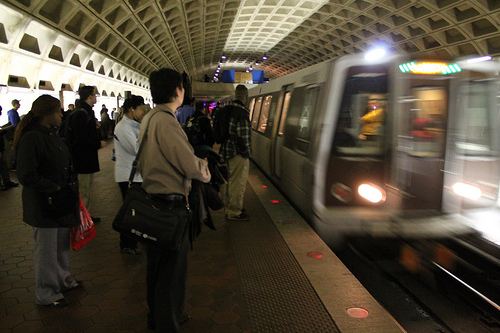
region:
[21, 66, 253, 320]
People standing at the train station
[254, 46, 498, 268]
Silver train on the tracks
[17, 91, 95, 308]
Woman holding a red bag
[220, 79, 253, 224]
Man wearing flannel shirt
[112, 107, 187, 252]
Bag over man's shoulder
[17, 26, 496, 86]
Domed ceiling of train station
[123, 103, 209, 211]
the shirt is brown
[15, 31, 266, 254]
people waiting for the train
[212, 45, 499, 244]
long underground passenger train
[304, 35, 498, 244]
front end of passenger train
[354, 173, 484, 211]
white lights on train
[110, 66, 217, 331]
person in tan sweater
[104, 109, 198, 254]
black bag hanging from shoulder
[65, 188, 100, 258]
red plastic shopping bag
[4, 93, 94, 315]
woman in black coat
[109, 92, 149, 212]
person in white coat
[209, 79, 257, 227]
person in plaid shirt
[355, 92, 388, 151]
passenger aboard moving train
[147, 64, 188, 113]
The man has black hair.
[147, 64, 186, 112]
The man has short hair.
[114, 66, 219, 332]
The man is standing on the platform.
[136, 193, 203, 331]
The man is wearing black pants.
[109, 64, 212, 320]
The man is carrying a bag.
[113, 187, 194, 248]
The bag is black in color.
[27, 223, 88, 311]
The woman is wearing gray pants.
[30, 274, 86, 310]
The woman is wearing black shoes.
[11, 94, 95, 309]
The woman is wearing a black jacket.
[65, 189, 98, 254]
The woman is holding a red bag.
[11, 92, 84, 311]
A long haired black woman with grey pants and a black coat.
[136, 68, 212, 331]
A black haired person in a tan coat and black pants.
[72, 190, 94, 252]
A red bag a black woman is holding.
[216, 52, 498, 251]
A long silver train.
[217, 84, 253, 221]
A dark man in a plaid shirt with tan pants.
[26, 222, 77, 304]
Grey pants on a black woman.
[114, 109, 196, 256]
A black bag with long strap on a man's right shoulder wearing a tan coat.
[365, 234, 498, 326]
Brown train tracks.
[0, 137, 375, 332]
Brown walkway people are standing on.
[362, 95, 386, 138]
A person standing in a train with yellow on.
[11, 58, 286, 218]
many people next to train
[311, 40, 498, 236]
back of the train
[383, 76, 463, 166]
window on back of train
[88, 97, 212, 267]
bag on person's side